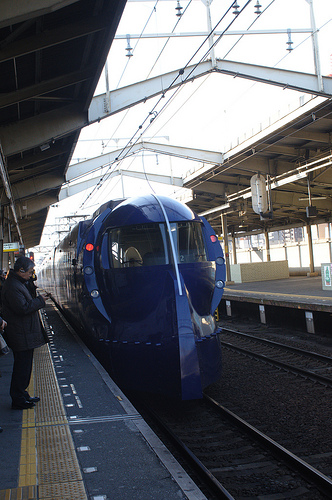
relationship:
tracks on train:
[160, 393, 294, 489] [68, 203, 232, 381]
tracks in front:
[160, 393, 294, 489] [231, 465, 327, 499]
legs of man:
[9, 351, 52, 410] [17, 250, 54, 362]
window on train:
[83, 218, 152, 258] [68, 203, 232, 381]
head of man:
[3, 253, 50, 282] [17, 250, 54, 362]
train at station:
[68, 203, 232, 381] [24, 77, 294, 428]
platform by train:
[50, 329, 149, 500] [68, 203, 232, 381]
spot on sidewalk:
[59, 404, 111, 449] [28, 374, 159, 483]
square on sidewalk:
[78, 421, 141, 473] [28, 374, 159, 483]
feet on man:
[20, 386, 50, 407] [2, 254, 55, 416]